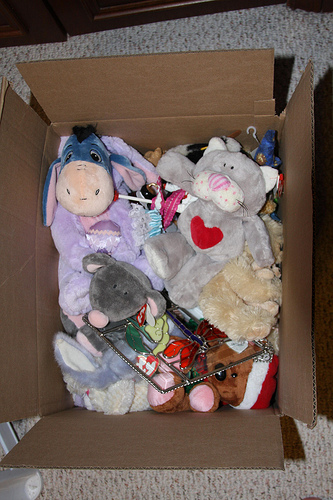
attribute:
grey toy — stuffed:
[142, 135, 274, 307]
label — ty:
[136, 355, 157, 374]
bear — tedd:
[157, 339, 284, 422]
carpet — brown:
[1, 5, 327, 106]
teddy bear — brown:
[170, 319, 269, 412]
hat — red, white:
[231, 338, 282, 416]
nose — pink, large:
[83, 301, 123, 329]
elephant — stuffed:
[194, 145, 268, 244]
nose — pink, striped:
[94, 186, 104, 196]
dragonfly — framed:
[160, 319, 231, 370]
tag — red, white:
[133, 354, 157, 379]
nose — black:
[213, 359, 227, 379]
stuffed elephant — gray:
[58, 249, 168, 359]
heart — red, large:
[185, 212, 237, 250]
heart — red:
[189, 214, 225, 250]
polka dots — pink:
[193, 172, 244, 204]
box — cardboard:
[49, 409, 285, 470]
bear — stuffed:
[136, 111, 299, 294]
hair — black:
[69, 120, 101, 141]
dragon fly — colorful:
[162, 307, 229, 372]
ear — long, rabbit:
[52, 329, 105, 377]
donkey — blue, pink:
[43, 122, 165, 306]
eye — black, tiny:
[225, 163, 226, 169]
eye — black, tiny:
[228, 163, 236, 172]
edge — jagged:
[1, 39, 317, 480]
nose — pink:
[87, 308, 109, 327]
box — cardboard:
[0, 49, 317, 471]